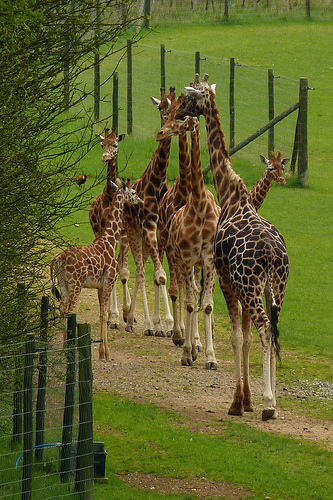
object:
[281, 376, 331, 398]
rocks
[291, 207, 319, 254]
floor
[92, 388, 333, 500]
grass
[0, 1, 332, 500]
ground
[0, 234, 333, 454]
dead grass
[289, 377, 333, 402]
pile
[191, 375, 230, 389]
rocks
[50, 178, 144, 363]
giraffe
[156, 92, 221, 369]
giraffe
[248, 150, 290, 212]
giraffe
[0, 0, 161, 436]
tree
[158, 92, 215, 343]
giraffe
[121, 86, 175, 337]
giraffe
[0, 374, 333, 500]
grass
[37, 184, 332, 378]
grass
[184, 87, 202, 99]
ear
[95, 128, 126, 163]
head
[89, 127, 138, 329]
giraffe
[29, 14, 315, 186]
fence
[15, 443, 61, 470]
hose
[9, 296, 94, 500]
curved fence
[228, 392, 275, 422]
hooves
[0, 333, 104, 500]
fence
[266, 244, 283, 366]
tail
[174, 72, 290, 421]
giraffe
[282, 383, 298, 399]
rocks